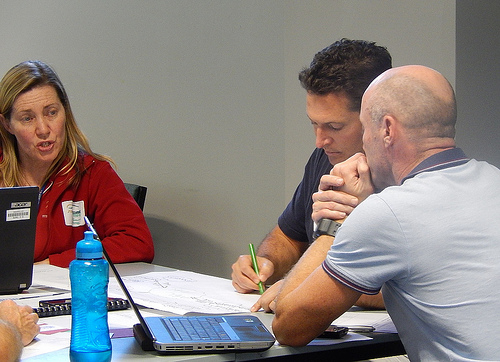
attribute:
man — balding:
[252, 38, 409, 313]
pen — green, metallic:
[247, 235, 264, 296]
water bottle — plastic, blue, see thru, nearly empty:
[67, 227, 115, 359]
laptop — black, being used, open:
[81, 211, 275, 355]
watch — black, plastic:
[309, 217, 342, 237]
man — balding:
[246, 65, 496, 361]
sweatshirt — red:
[5, 155, 154, 274]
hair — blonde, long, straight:
[0, 65, 95, 192]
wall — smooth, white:
[2, 3, 471, 316]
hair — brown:
[289, 25, 393, 107]